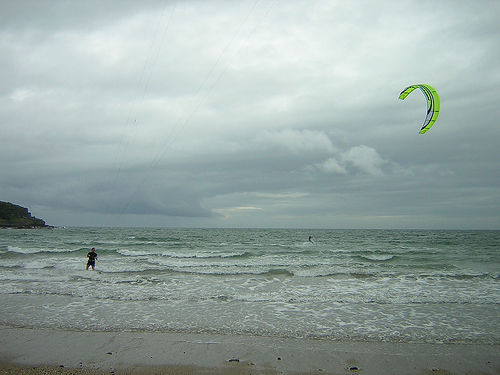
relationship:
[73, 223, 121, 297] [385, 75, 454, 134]
man flying kite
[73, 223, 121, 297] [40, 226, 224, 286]
man in water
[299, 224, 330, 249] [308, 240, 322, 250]
person on surfboard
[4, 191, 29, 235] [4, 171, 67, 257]
part of land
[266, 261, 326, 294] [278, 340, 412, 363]
waves by shore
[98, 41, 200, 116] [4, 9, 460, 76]
clouds in sky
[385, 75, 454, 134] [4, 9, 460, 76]
kite in sky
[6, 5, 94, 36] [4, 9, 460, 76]
no birds in sky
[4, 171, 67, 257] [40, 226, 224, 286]
land by water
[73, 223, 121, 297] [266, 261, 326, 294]
man in waves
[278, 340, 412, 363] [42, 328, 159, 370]
shore has sand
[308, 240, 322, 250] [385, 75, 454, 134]
surfboard on kite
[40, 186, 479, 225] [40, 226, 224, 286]
horizon over water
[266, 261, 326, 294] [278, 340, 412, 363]
waves on shore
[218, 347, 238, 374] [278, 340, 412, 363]
rock on shore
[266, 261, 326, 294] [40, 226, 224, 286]
waves in water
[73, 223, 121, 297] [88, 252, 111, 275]
man wearing black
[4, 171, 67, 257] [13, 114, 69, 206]
land on left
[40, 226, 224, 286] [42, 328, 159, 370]
water on sand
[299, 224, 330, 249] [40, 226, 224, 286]
person in water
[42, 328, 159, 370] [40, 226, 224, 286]
sand by water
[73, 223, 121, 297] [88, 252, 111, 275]
man in black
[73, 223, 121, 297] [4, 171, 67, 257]
man by land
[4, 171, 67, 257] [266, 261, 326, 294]
land close to waves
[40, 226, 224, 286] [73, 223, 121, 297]
water with man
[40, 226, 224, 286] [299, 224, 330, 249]
water with person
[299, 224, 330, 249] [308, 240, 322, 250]
person with surfboard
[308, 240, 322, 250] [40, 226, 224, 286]
surfboard with water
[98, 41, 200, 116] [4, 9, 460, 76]
clouds i sky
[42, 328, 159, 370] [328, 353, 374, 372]
sand with seaweed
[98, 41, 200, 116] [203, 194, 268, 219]
clouds coverig su